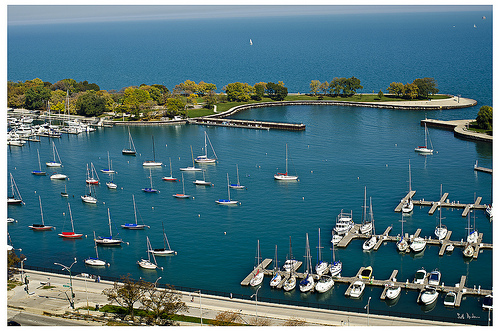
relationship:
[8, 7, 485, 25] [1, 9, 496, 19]
cloud hanging in sky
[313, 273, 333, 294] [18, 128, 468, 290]
boat sitting in water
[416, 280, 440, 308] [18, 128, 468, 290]
boat sitting in water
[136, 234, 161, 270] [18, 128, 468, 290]
boat sitting in water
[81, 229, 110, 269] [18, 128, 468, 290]
boat sitting in water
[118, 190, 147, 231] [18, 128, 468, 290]
boat sitting in water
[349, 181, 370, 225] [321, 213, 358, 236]
mast built on top of boat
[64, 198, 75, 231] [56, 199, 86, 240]
mast built on top of boat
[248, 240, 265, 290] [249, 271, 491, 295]
boat parked at dock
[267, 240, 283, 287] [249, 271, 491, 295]
boat parked at dock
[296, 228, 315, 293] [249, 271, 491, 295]
boat parked at dock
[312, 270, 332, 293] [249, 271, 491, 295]
boat parked at dock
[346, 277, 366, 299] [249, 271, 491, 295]
boat parked at dock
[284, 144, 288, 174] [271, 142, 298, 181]
mast built on top of boat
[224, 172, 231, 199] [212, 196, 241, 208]
mast built on top of boat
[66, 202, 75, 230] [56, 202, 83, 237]
mast built on top of boat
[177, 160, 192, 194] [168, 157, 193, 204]
mast built on top of boat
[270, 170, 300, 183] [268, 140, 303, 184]
mast built on top of boat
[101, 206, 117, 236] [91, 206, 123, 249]
mast built on top of boat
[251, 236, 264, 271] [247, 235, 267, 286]
mast built on top of boat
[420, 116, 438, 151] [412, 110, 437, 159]
mast built on top of boat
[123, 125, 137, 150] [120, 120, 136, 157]
mast built on top of boat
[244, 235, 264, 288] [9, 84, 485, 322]
boat lying in harbor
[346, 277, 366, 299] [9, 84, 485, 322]
boat lying in harbor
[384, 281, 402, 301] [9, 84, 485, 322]
boat lying in harbor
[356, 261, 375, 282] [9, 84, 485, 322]
boat lying in harbor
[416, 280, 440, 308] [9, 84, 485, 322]
boat lying in harbor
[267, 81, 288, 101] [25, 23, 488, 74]
tree standing near water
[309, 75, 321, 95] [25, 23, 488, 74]
tree standing near water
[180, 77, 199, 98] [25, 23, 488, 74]
tree standing near water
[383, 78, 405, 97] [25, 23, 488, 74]
tree standing near water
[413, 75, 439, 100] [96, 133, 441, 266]
tree standing near water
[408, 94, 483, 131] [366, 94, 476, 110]
water flowing to beach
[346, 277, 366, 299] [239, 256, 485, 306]
boat anchored at dock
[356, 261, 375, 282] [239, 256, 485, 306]
boat anchored at dock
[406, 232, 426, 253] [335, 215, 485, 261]
boat anchored at dock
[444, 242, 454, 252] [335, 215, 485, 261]
boat anchored at dock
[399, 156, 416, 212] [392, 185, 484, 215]
boat anchored at dock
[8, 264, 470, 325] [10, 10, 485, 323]
road built near water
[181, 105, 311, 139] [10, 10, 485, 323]
pier jutting into water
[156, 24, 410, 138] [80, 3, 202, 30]
clouds hanging in sky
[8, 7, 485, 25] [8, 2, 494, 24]
cloud hanging in blue sky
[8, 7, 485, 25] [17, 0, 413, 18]
cloud hanging in sky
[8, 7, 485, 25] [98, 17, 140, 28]
cloud hanging in sky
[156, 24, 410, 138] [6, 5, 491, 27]
clouds in blue sky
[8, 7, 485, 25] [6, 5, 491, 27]
cloud in blue sky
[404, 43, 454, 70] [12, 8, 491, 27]
clouds in sky